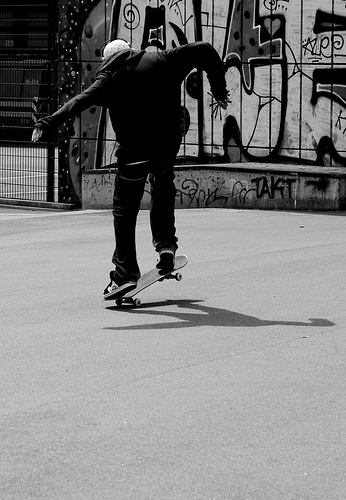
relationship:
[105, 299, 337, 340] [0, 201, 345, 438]
shadow on ground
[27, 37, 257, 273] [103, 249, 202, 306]
man on board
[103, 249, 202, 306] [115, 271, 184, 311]
board has wheels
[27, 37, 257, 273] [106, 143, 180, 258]
man in pants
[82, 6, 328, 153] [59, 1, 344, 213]
graffiti on wall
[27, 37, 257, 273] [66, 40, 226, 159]
man in shirt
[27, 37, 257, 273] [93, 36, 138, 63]
man in headphones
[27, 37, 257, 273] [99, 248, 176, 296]
man in shoes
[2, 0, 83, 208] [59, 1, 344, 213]
fence by wall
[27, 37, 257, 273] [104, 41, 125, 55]
man in hat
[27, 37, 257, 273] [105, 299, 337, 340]
man casting shadow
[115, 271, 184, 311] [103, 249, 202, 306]
wheels on board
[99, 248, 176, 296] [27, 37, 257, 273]
shoes on man